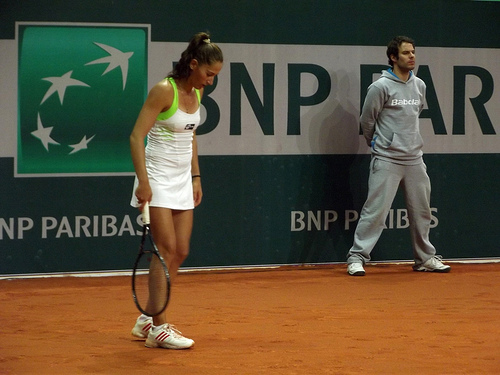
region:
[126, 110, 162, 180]
arm of a person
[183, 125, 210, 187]
arm of a person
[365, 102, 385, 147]
arm of a person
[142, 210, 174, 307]
leg of a person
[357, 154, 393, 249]
leg of a person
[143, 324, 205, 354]
feet of a person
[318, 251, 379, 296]
feet of a person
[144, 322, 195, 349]
a red and white tennis shoe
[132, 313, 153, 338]
a red and white tennis shoe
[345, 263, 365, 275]
a white tennis shoe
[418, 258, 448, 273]
a white tennis shoe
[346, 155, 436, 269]
a pair of grey sweatpants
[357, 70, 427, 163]
a grey sweatshirt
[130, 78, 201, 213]
a white and green tennis skirt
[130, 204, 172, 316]
a white and black tennis racket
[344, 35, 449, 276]
a man standing on court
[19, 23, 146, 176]
a green and white logo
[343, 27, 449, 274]
man is standing still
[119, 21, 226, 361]
woman is playing tennis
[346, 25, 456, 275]
man is wearing sweatpants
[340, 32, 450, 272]
man has dark hair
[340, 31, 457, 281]
man is wearing white shoes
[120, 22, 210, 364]
woman is holding tennis racket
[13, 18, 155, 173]
logo is green and white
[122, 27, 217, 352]
woman has hair in ponytail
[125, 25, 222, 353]
woman is wearing white and red shoes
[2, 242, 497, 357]
ground is clay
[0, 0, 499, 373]
the interior of a tennis arena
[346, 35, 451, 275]
a tennis ball boy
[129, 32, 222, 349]
a woman playing tennis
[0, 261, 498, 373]
a dirt tennis court surface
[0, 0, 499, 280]
advertisements on the wall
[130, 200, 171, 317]
the woman's tennis racket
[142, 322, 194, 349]
the woman's right tennis shoe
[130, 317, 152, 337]
the woman's left tennis shoe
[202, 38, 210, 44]
the woman's hair scrunchie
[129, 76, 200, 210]
the woman's tennis uniform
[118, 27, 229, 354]
woman is playing tennis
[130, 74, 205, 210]
woman wearing a dress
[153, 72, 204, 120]
dress has green straps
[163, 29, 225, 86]
woman's hair in pony tail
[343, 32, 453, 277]
man's arms behind his back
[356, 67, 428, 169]
man's shirt is gray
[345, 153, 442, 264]
man's pants are gray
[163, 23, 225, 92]
woman is looking down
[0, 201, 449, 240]
white letters on wall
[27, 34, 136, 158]
white stars on wall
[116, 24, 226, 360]
A woman looking down.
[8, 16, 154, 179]
A green sign with white stars on it.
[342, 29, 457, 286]
A man standing by the wall.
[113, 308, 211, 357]
A woman wearing white tennis shoes with red stripes.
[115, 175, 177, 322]
A woman holding a tennis racket in her right hand.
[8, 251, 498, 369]
CLAY COURT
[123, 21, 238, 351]
FEMALE TENNIS PLAYER ON THE COURT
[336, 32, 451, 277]
A MAN STANDING ON THE TENNIS COURT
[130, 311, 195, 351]
WHITE SHOES WITH RED STRIPES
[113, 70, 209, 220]
WHITE TENNIS UNIFORM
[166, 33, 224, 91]
HAIR TIED IN PONY TAIL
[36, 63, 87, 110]
WHITE STAR IN GREEN BACKGROUND